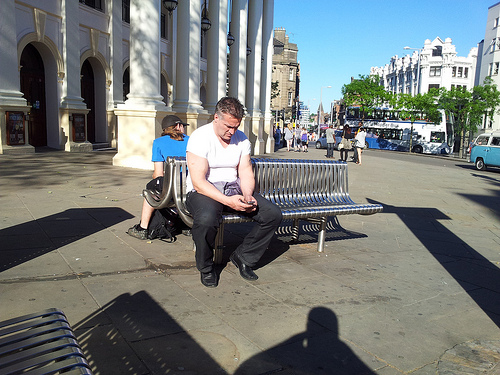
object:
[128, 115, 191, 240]
person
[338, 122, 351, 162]
person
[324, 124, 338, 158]
person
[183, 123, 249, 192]
shirt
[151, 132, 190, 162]
shirt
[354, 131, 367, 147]
shirt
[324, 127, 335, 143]
shirt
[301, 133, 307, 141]
shirt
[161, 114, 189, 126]
cap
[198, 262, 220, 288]
shoes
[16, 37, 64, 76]
arch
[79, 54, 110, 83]
arch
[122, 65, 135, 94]
arch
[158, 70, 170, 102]
arch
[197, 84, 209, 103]
arch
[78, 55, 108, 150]
entrances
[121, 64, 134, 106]
entrances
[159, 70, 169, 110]
entrances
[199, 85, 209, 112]
entrances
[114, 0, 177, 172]
pillars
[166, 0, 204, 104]
pillars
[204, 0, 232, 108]
pillars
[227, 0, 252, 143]
pillars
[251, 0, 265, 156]
pillars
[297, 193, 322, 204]
grey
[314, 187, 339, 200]
metal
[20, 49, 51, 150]
wooden door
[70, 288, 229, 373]
shadow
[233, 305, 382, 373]
shadow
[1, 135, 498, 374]
ground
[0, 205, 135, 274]
shadow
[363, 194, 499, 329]
shadow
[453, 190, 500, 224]
shadow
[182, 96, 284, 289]
guy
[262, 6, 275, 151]
pillars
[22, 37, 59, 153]
doorways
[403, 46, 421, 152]
street lamp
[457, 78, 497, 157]
tree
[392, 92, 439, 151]
tree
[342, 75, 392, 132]
tree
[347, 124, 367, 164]
walking people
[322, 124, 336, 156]
walking people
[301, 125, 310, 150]
walking people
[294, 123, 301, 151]
walking people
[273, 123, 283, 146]
walking people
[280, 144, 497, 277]
street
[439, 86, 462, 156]
trees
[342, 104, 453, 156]
bus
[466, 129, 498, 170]
volkswagon bus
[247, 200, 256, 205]
cell phone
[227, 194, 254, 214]
hands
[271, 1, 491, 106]
sky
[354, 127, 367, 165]
people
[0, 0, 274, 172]
building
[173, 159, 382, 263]
bench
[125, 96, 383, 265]
bench/person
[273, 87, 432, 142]
background